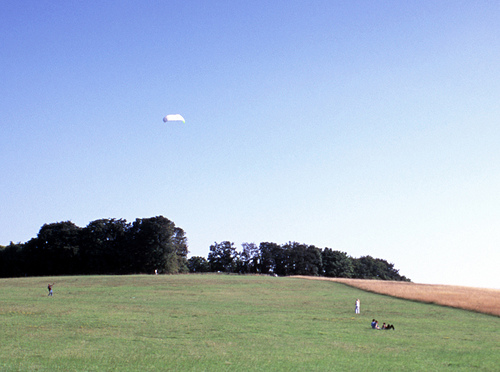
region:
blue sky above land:
[180, 17, 301, 100]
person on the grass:
[341, 280, 376, 320]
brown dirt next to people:
[450, 280, 480, 305]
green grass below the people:
[216, 291, 281, 332]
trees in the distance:
[105, 195, 180, 265]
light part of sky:
[415, 200, 480, 245]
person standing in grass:
[35, 275, 67, 310]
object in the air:
[131, 101, 213, 161]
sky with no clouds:
[276, 40, 356, 105]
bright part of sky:
[448, 242, 490, 272]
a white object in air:
[134, 99, 208, 141]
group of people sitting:
[342, 290, 399, 353]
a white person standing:
[348, 287, 365, 319]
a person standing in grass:
[34, 264, 67, 306]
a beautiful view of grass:
[3, 258, 498, 368]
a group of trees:
[20, 217, 400, 296]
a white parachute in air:
[143, 92, 198, 135]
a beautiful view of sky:
[11, 22, 491, 223]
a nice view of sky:
[34, 25, 478, 239]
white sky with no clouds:
[31, 21, 491, 231]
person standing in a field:
[41, 278, 68, 306]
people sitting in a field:
[367, 315, 400, 336]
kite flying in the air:
[161, 103, 190, 127]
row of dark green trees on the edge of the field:
[6, 211, 430, 288]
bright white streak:
[166, 111, 191, 124]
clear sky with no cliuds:
[1, 1, 478, 283]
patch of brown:
[331, 268, 498, 316]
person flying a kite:
[34, 103, 204, 310]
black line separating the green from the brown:
[345, 285, 498, 325]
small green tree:
[186, 254, 206, 274]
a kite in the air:
[119, 91, 235, 166]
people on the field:
[284, 259, 425, 369]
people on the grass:
[310, 282, 410, 342]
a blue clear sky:
[60, 45, 115, 96]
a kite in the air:
[87, 47, 342, 247]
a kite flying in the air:
[82, 52, 354, 223]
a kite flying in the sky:
[114, 50, 275, 170]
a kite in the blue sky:
[48, 35, 390, 189]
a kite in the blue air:
[68, 27, 305, 209]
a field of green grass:
[89, 284, 296, 369]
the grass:
[123, 263, 285, 368]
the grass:
[140, 231, 292, 340]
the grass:
[155, 255, 245, 360]